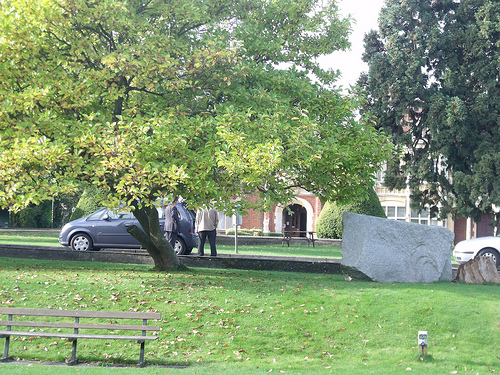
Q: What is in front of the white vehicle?
A: A large rock.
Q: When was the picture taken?
A: Daytime.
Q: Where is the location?
A: School.